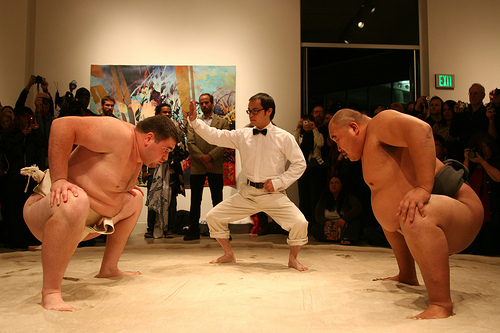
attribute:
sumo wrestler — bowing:
[319, 102, 490, 321]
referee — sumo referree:
[185, 83, 322, 281]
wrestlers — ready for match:
[17, 95, 490, 320]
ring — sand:
[2, 242, 497, 332]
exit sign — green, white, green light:
[432, 72, 458, 92]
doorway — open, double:
[300, 41, 421, 121]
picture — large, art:
[85, 62, 237, 189]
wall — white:
[27, 5, 295, 230]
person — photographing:
[298, 99, 333, 207]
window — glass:
[302, 4, 424, 45]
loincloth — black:
[427, 149, 472, 198]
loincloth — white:
[20, 163, 116, 239]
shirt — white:
[190, 111, 306, 192]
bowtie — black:
[250, 128, 267, 138]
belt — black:
[246, 176, 269, 189]